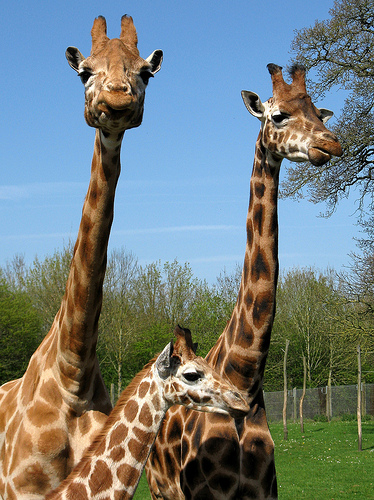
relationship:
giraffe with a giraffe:
[41, 324, 250, 500] [143, 63, 342, 499]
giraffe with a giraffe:
[41, 324, 250, 500] [0, 14, 163, 500]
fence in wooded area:
[262, 383, 373, 423] [0, 235, 373, 450]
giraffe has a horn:
[143, 63, 342, 499] [290, 64, 307, 92]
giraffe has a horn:
[143, 63, 342, 499] [266, 63, 286, 89]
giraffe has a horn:
[41, 324, 250, 500] [173, 324, 185, 348]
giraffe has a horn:
[41, 324, 250, 500] [182, 328, 194, 349]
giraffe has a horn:
[0, 14, 163, 500] [120, 14, 138, 48]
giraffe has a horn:
[0, 14, 163, 500] [91, 15, 107, 49]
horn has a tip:
[290, 64, 307, 92] [289, 64, 306, 74]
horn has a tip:
[266, 63, 286, 89] [267, 63, 281, 75]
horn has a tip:
[182, 328, 194, 349] [182, 327, 192, 334]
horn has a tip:
[173, 324, 185, 348] [174, 324, 184, 336]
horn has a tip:
[120, 14, 138, 48] [121, 14, 132, 23]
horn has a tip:
[91, 15, 107, 49] [94, 14, 106, 22]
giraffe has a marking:
[143, 63, 342, 499] [253, 181, 265, 200]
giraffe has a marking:
[143, 63, 342, 499] [251, 202, 265, 236]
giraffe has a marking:
[143, 63, 342, 499] [249, 244, 271, 284]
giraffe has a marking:
[143, 63, 342, 499] [252, 289, 273, 330]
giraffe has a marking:
[143, 63, 342, 499] [243, 289, 253, 312]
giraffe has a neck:
[143, 63, 342, 499] [203, 141, 282, 400]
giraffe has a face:
[0, 14, 163, 500] [77, 55, 155, 128]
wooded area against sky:
[0, 235, 373, 450] [0, 1, 373, 322]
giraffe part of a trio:
[143, 63, 342, 499] [0, 13, 344, 499]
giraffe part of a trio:
[41, 324, 250, 500] [0, 13, 344, 499]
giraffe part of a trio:
[0, 14, 163, 500] [0, 13, 344, 499]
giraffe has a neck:
[41, 324, 250, 500] [43, 367, 174, 500]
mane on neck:
[43, 351, 161, 499] [43, 367, 174, 500]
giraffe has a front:
[143, 63, 342, 499] [201, 391, 278, 500]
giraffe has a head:
[143, 63, 342, 499] [241, 63, 343, 167]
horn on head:
[266, 63, 286, 89] [241, 63, 343, 167]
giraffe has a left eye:
[0, 14, 163, 500] [136, 69, 154, 85]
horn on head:
[290, 64, 307, 92] [241, 63, 343, 167]